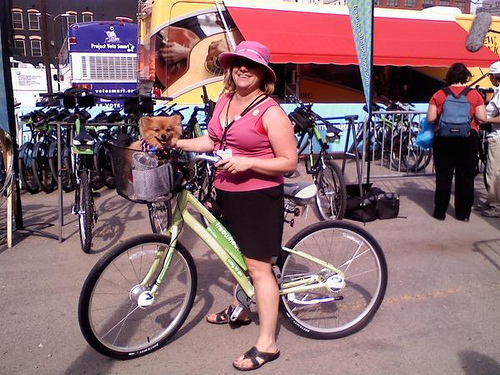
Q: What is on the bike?
A: Dog.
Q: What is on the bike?
A: Dog in basket.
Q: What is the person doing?
A: Riding bike.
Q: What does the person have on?
A: Pink shirt.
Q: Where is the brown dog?
A: In the basket.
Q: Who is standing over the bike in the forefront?
A: The woman.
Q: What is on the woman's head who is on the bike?
A: Pink hat.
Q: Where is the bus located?
A: Behind bicycles on left.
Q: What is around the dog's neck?
A: Bandana.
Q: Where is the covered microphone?
A: Top right.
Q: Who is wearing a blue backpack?
A: The woman in the background.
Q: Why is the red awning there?
A: To provide shade.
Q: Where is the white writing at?
A: Back of bus.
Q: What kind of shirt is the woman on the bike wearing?
A: A pink sleeveless shirt.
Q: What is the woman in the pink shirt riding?
A: A bicycle.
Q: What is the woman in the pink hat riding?
A: A light green framed bicycle.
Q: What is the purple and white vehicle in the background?
A: A purple and white bus.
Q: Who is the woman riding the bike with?
A: A dog.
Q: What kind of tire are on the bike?
A: Thin black tires.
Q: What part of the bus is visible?
A: The back.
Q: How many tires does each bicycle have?
A: Two.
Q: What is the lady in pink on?
A: A bicycle.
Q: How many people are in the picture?
A: Three.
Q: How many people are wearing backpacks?
A: One.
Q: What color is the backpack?
A: Blue.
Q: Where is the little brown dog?
A: In the basket on the green bike.